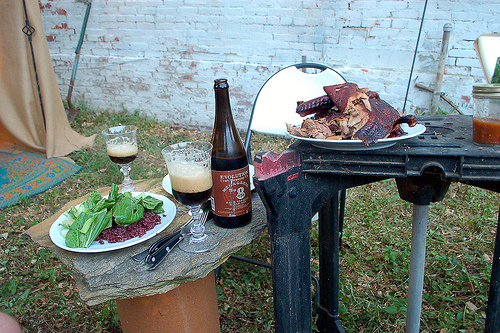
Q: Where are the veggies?
A: On the plate.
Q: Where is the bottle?
A: On a stone.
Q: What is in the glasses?
A: Soda.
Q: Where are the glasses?
A: On the stone.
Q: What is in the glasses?
A: Drinks.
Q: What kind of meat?
A: Ribs.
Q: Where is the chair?
A: On the grass.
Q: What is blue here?
A: The wall.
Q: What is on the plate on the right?
A: Cooked meat.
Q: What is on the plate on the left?
A: Greens.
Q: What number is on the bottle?
A: 8.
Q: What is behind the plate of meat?
A: A chair.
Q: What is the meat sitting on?
A: A white plate.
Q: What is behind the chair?
A: A wall.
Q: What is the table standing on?
A: Grass.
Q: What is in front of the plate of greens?
A: Silverware.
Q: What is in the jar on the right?
A: Sauce.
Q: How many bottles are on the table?
A: One.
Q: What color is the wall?
A: Blue.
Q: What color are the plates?
A: White.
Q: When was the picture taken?
A: During the day.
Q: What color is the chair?
A: White.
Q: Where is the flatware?
A: On the stone.